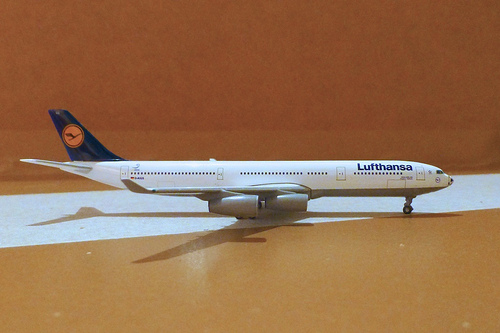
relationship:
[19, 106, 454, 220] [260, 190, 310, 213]
aircraft has engine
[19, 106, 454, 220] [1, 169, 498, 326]
aircraft on ground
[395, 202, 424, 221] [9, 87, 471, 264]
gear of aircraft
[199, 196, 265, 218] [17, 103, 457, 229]
engine of aircraft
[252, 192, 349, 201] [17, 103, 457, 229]
engine of aircraft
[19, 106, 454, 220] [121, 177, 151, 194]
aircraft has wing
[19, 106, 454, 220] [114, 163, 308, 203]
aircraft has wing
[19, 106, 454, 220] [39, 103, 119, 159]
aircraft has tail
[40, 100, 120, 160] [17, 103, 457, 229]
rudder on aircraft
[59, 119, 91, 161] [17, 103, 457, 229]
logo in aircraft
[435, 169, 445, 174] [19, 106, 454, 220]
cockpit wondow in aircraft